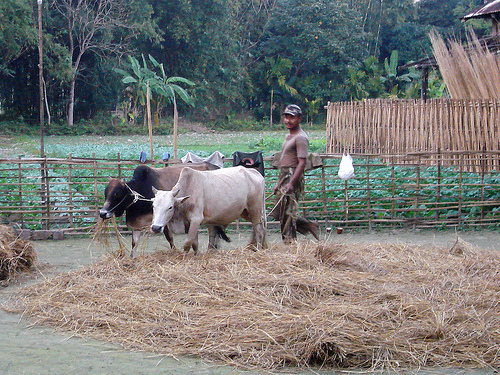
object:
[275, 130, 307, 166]
shirt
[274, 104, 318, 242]
man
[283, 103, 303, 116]
hat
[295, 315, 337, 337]
straw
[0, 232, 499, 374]
ground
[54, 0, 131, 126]
tree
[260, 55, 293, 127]
tree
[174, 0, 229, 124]
tree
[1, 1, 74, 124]
tree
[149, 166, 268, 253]
cow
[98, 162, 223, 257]
cow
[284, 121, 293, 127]
mustache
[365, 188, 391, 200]
plant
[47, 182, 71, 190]
plant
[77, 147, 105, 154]
plant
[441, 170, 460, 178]
plant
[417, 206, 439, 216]
plant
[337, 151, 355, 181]
bag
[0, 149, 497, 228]
fence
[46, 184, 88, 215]
crop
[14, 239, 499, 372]
pile of hay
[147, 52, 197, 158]
palm tree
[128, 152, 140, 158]
crop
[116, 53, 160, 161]
palm tree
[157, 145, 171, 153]
crop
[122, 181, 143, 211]
rope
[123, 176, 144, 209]
cow's neck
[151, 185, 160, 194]
horns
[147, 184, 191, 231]
cow's head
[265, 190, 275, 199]
stick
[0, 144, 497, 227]
vegetable garden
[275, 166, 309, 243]
pants